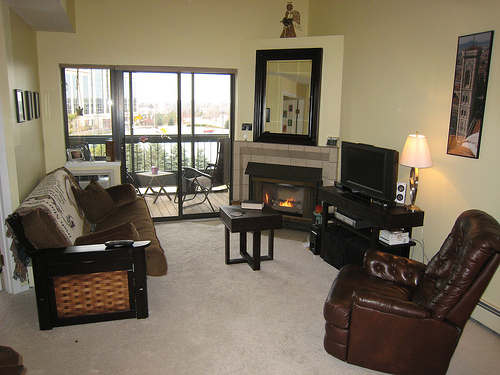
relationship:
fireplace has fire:
[232, 142, 341, 228] [265, 191, 298, 210]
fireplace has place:
[232, 142, 341, 228] [263, 185, 304, 215]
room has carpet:
[0, 2, 488, 370] [0, 217, 498, 371]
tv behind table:
[339, 137, 401, 208] [220, 199, 285, 272]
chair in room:
[324, 211, 494, 375] [0, 2, 488, 370]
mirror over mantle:
[253, 47, 319, 147] [232, 132, 341, 162]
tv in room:
[339, 137, 401, 208] [0, 2, 488, 370]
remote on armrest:
[104, 235, 140, 247] [29, 235, 151, 261]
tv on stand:
[339, 137, 401, 208] [314, 180, 428, 269]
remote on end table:
[104, 235, 140, 247] [28, 241, 151, 330]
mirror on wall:
[253, 47, 319, 147] [245, 34, 345, 144]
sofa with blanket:
[9, 168, 170, 280] [19, 168, 85, 246]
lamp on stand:
[400, 135, 433, 215] [314, 180, 428, 269]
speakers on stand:
[394, 184, 408, 207] [314, 180, 428, 269]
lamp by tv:
[400, 135, 433, 215] [339, 137, 401, 208]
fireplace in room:
[232, 142, 341, 228] [0, 2, 488, 370]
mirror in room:
[253, 47, 319, 147] [0, 2, 488, 370]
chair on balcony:
[186, 136, 232, 189] [66, 72, 236, 224]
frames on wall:
[15, 89, 43, 125] [1, 29, 46, 222]